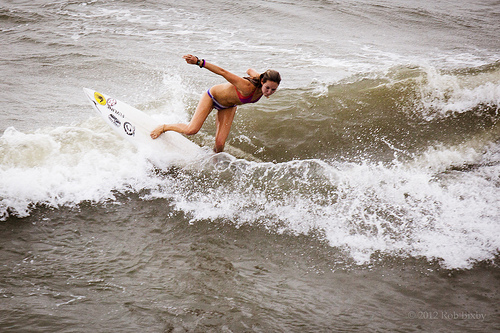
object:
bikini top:
[235, 77, 263, 105]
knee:
[183, 127, 201, 136]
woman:
[149, 54, 281, 163]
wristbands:
[199, 59, 205, 69]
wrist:
[196, 59, 206, 69]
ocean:
[0, 0, 500, 333]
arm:
[202, 60, 252, 92]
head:
[260, 71, 281, 97]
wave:
[0, 30, 499, 276]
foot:
[150, 125, 167, 140]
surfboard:
[84, 87, 209, 177]